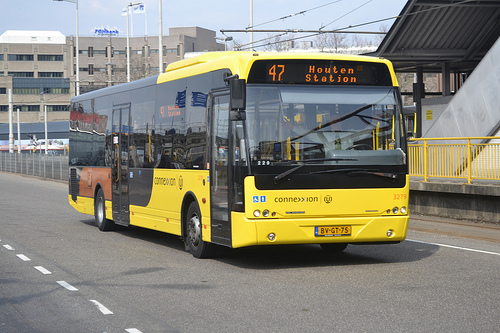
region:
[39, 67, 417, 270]
The bus is yellow.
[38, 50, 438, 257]
The yellow bus on the street.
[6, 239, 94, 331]
White lines in the road.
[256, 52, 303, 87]
The bus number is 47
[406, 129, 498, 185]
The railing on the walkway.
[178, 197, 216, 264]
A tire on tht bus.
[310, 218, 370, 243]
The yellow license plate in front of bus.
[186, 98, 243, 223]
The door of the bus.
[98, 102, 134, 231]
The back door of the bus.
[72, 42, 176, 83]
Windows on the building.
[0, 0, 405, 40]
blue of daytime sky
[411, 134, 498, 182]
yellow rails of fence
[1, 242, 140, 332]
white broken lines on street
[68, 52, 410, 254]
bus on paved street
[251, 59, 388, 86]
words and numbers on display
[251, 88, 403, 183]
windshield on front of bus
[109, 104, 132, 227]
double doors on side of bus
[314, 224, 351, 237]
yellow license plate on bus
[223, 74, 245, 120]
side view mirror on bus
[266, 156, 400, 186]
two black windshield wipers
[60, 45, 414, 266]
A yellow public bus on a road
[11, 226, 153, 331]
lines on the road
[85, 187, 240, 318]
wheels on the bus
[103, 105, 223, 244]
doors on the bus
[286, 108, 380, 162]
the man is bus driver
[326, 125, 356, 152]
tie on the shirt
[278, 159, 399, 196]
wipers on the bus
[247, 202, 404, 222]
lights on the bus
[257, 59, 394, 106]
screen is on the bus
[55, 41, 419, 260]
A yellow public bus on a road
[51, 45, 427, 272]
A yellow public bus on a road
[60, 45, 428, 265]
A yellow public bus on a road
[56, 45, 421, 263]
A yellow public bus on a road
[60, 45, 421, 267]
A yellow public bus on a road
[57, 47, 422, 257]
A yellow public bus on a road